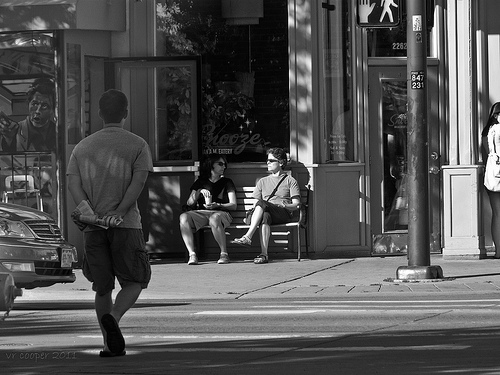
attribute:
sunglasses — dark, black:
[258, 153, 289, 175]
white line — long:
[193, 306, 330, 318]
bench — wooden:
[169, 174, 301, 251]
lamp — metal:
[383, 2, 472, 294]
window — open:
[152, 62, 206, 175]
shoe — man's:
[104, 307, 171, 355]